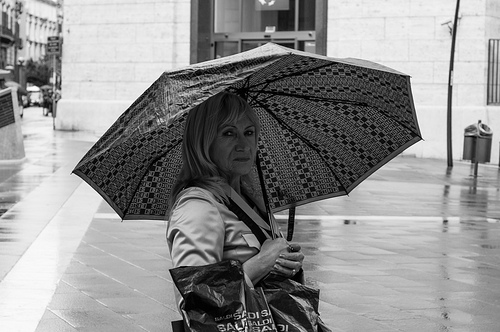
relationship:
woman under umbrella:
[160, 85, 309, 328] [69, 37, 429, 224]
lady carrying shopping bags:
[165, 90, 302, 330] [166, 253, 328, 329]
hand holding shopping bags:
[271, 244, 305, 279] [166, 253, 328, 329]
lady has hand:
[165, 90, 302, 330] [271, 244, 305, 279]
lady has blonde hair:
[165, 90, 302, 330] [167, 87, 224, 196]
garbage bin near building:
[470, 117, 493, 165] [0, 5, 500, 172]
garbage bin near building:
[460, 121, 475, 161] [0, 5, 500, 172]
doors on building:
[211, 29, 317, 56] [44, 15, 487, 165]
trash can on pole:
[463, 120, 493, 162] [471, 160, 481, 180]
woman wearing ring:
[160, 85, 309, 328] [291, 268, 297, 276]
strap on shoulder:
[178, 185, 267, 245] [166, 182, 227, 257]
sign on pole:
[45, 33, 67, 60] [49, 50, 57, 132]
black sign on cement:
[0, 91, 20, 126] [1, 156, 33, 198]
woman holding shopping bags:
[183, 93, 308, 328] [166, 253, 328, 329]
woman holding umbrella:
[160, 85, 309, 328] [69, 37, 429, 224]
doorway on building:
[190, 2, 328, 62] [0, 5, 500, 172]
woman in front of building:
[169, 100, 330, 331] [0, 5, 500, 172]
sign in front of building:
[263, 23, 279, 34] [0, 5, 500, 172]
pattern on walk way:
[82, 239, 119, 281] [0, 105, 499, 330]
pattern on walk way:
[394, 166, 444, 199] [0, 105, 499, 330]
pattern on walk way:
[317, 220, 367, 267] [0, 105, 499, 330]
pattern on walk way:
[134, 277, 162, 315] [0, 105, 499, 330]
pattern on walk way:
[431, 258, 480, 314] [0, 105, 499, 330]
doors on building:
[211, 29, 317, 56] [0, 5, 500, 172]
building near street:
[0, 0, 24, 84] [19, 104, 56, 120]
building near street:
[25, 1, 60, 67] [19, 104, 56, 120]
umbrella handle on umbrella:
[238, 92, 283, 239] [69, 37, 429, 224]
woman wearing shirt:
[166, 86, 324, 331] [164, 178, 287, 306]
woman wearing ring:
[160, 85, 309, 328] [290, 267, 295, 274]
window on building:
[212, 3, 319, 38] [0, 5, 500, 172]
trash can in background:
[461, 118, 496, 165] [4, 1, 499, 169]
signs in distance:
[35, 29, 66, 139] [2, 0, 499, 162]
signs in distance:
[47, 36, 60, 42] [2, 0, 499, 162]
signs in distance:
[46, 40, 60, 47] [2, 0, 499, 162]